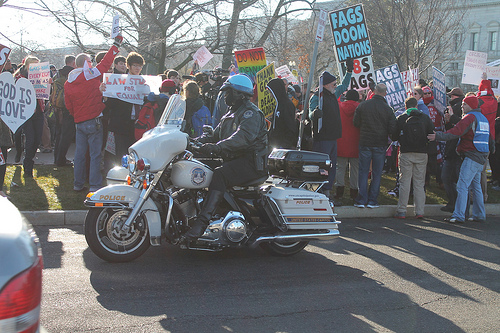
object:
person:
[427, 95, 489, 223]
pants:
[451, 156, 487, 222]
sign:
[0, 71, 37, 135]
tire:
[85, 195, 155, 263]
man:
[352, 82, 400, 209]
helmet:
[219, 74, 254, 97]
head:
[219, 74, 255, 106]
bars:
[188, 126, 270, 161]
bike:
[82, 94, 341, 264]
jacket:
[63, 45, 120, 123]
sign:
[327, 4, 375, 93]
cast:
[362, 225, 494, 307]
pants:
[396, 152, 428, 216]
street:
[30, 217, 499, 332]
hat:
[463, 96, 479, 109]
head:
[461, 96, 479, 115]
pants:
[208, 151, 268, 193]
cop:
[190, 74, 270, 254]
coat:
[201, 100, 268, 160]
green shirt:
[245, 262, 362, 329]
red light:
[137, 158, 145, 170]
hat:
[319, 71, 336, 86]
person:
[337, 89, 360, 200]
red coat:
[337, 109, 360, 158]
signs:
[374, 63, 408, 110]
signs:
[234, 47, 267, 77]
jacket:
[309, 87, 343, 140]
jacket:
[337, 100, 361, 158]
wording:
[99, 195, 126, 201]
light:
[121, 154, 134, 169]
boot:
[184, 187, 225, 238]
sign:
[100, 73, 163, 105]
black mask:
[222, 92, 243, 106]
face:
[223, 87, 237, 105]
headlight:
[128, 152, 137, 174]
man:
[390, 96, 435, 219]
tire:
[259, 238, 311, 257]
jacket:
[352, 94, 400, 147]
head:
[319, 70, 337, 94]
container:
[260, 186, 341, 232]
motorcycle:
[83, 94, 341, 264]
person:
[307, 56, 353, 203]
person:
[264, 78, 298, 149]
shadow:
[80, 253, 468, 332]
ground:
[64, 218, 446, 324]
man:
[63, 32, 123, 196]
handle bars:
[185, 136, 216, 157]